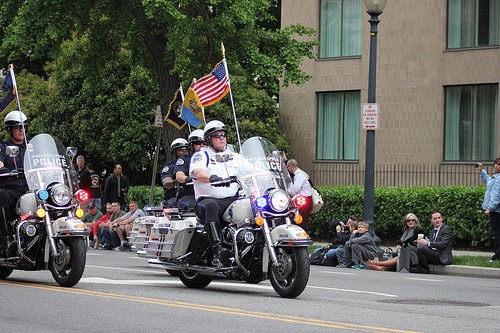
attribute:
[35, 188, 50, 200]
lights — on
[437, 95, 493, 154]
blind — open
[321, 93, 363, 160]
blind — closed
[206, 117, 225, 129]
helmet — white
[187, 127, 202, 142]
helmet — white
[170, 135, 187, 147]
helmet — white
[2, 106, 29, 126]
helmet — white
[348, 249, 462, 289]
line — white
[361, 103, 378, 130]
sign — red, white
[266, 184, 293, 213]
light — round, white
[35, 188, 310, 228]
police lights — flashing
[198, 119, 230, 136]
helmet — white, black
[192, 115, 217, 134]
helmet — white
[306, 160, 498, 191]
fence — steel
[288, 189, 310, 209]
light — red